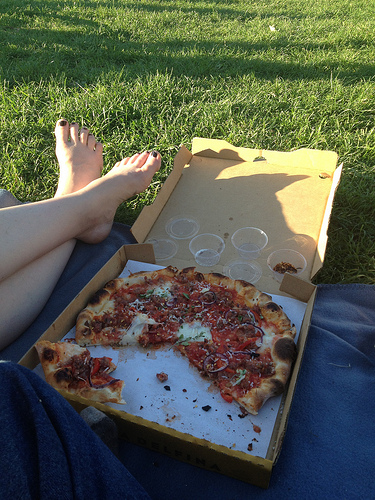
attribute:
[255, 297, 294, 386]
pizza — well-browned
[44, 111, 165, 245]
feet — bare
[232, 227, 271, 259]
container — clear, plastic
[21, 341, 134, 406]
slice — half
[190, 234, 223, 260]
containers — Small 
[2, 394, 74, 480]
denim — worn, touching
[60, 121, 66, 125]
nail polish — black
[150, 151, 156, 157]
nail polish — black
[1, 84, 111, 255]
female — leg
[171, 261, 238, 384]
pizza — slice, eaten